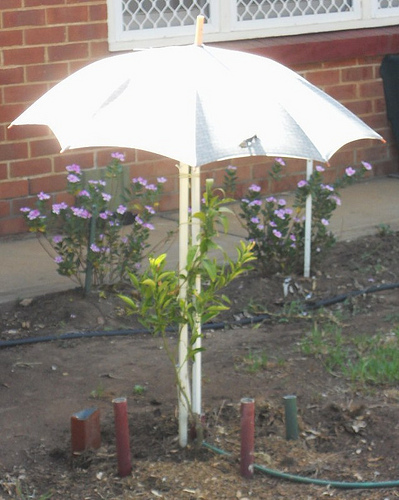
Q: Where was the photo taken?
A: It was taken at the sidewalk.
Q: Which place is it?
A: It is a sidewalk.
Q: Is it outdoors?
A: Yes, it is outdoors.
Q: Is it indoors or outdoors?
A: It is outdoors.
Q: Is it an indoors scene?
A: No, it is outdoors.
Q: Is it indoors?
A: No, it is outdoors.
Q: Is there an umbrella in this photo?
A: Yes, there is an umbrella.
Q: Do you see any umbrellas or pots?
A: Yes, there is an umbrella.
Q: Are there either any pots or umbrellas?
A: Yes, there is an umbrella.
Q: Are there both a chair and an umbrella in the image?
A: No, there is an umbrella but no chairs.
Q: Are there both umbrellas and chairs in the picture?
A: No, there is an umbrella but no chairs.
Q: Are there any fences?
A: No, there are no fences.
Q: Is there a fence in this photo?
A: No, there are no fences.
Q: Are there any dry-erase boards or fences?
A: No, there are no fences or dry-erase boards.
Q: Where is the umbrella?
A: The umbrella is in the garden.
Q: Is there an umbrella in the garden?
A: Yes, there is an umbrella in the garden.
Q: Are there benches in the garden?
A: No, there is an umbrella in the garden.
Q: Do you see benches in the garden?
A: No, there is an umbrella in the garden.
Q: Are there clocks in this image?
A: No, there are no clocks.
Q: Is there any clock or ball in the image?
A: No, there are no clocks or balls.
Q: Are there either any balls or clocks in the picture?
A: No, there are no clocks or balls.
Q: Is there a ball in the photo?
A: No, there are no balls.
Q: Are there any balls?
A: No, there are no balls.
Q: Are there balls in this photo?
A: No, there are no balls.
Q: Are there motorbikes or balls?
A: No, there are no balls or motorbikes.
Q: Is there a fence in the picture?
A: No, there are no fences.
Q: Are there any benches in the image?
A: No, there are no benches.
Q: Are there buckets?
A: No, there are no buckets.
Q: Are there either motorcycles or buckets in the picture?
A: No, there are no buckets or motorcycles.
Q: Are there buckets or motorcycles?
A: No, there are no buckets or motorcycles.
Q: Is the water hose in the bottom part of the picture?
A: Yes, the water hose is in the bottom of the image.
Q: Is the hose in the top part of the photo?
A: No, the hose is in the bottom of the image.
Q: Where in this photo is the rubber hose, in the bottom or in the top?
A: The hose is in the bottom of the image.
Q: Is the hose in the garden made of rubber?
A: Yes, the hose is made of rubber.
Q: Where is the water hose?
A: The water hose is in the garden.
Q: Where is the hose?
A: The water hose is in the garden.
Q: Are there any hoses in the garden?
A: Yes, there is a hose in the garden.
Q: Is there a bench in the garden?
A: No, there is a hose in the garden.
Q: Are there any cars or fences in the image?
A: No, there are no fences or cars.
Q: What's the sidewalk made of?
A: The sidewalk is made of concrete.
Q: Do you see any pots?
A: No, there are no pots.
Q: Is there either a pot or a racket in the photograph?
A: No, there are no pots or rackets.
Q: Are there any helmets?
A: No, there are no helmets.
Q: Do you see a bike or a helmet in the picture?
A: No, there are no helmets or bikes.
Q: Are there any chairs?
A: No, there are no chairs.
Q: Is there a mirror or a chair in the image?
A: No, there are no chairs or mirrors.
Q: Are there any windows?
A: Yes, there is a window.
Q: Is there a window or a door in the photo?
A: Yes, there is a window.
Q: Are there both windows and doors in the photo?
A: No, there is a window but no doors.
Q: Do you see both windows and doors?
A: No, there is a window but no doors.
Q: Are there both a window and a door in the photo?
A: No, there is a window but no doors.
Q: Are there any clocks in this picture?
A: No, there are no clocks.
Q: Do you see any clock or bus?
A: No, there are no clocks or buses.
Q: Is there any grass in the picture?
A: Yes, there is grass.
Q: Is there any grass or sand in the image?
A: Yes, there is grass.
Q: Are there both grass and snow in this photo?
A: No, there is grass but no snow.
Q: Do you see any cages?
A: No, there are no cages.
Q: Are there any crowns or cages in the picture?
A: No, there are no cages or crowns.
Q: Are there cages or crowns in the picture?
A: No, there are no cages or crowns.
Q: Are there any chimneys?
A: No, there are no chimneys.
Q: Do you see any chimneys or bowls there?
A: No, there are no chimneys or bowls.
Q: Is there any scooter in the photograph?
A: No, there are no scooters.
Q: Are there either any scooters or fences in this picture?
A: No, there are no scooters or fences.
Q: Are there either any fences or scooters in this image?
A: No, there are no scooters or fences.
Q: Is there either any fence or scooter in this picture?
A: No, there are no scooters or fences.